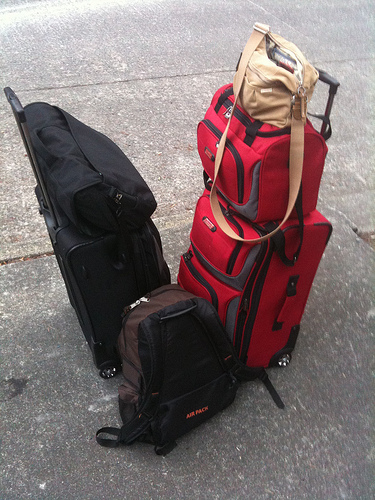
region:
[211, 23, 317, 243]
A small carrying bag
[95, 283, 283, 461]
A brown and black book bag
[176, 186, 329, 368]
Red luggage bag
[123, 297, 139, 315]
Zipper on a backpack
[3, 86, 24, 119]
Top handle of a luggage bag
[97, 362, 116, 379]
Small wheel on a bag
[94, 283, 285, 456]
A brown book bag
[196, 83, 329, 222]
A red luggage bag on top of a bigger one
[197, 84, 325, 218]
the case is red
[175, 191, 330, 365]
piece of red luggage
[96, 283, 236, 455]
backpack on the floor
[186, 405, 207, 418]
the text is orange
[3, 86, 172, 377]
the luggage is black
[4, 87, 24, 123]
the handle is black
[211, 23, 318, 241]
the purse is khaki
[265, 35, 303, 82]
the purse is unzipped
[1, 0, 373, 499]
the ground is gray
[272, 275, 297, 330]
red and black handle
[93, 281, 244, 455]
brown backpack going onboard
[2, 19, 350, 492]
luggage sitting on the street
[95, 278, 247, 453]
full brown backpack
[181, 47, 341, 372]
two red suitcases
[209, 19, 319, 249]
medium sized woman's purse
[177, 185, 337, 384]
one red roll around case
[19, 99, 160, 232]
laptop bag for man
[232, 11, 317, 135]
brown bag on red bags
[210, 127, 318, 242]
brown strap of bag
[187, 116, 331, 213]
small red suitcase on top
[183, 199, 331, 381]
red suitcase on the bottom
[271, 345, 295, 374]
wheel on the suitcase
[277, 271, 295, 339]
handle of red suitcase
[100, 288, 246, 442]
brown backpack on ground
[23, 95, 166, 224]
black bag on ground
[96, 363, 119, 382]
wheel on the black bag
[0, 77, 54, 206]
handle on black suitcase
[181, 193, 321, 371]
A bag of luggage.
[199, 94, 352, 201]
A bag of luggage.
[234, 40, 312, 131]
A bag of luggage.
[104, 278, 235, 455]
A bag of luggage.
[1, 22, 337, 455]
Luggage on the sidewalk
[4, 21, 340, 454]
Luggage, a backpack, and a purse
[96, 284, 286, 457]
Brown and Black Backpack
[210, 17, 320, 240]
An open, tan purse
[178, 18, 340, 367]
Tan purse on two pieces of red luggage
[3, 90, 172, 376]
Black rolling luggage with a carry on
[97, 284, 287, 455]
Brown and black Air Pack backpack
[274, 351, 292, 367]
Rolling luggage wheel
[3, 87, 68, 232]
Black rolling luggage handle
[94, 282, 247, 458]
a black and brown backpack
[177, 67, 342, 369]
a red suitcase with a bag on top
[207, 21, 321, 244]
a tan bag with a long strap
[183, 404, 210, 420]
an orange logo on a backpack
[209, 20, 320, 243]
a tan purse that is open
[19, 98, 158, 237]
a black bag on top of a suitcase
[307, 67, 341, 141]
a black suitcase handle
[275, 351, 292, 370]
a wheel on a suitcase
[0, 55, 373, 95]
a crack in the sidewalk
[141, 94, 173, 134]
the side walk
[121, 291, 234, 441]
a backpack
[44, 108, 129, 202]
a bag